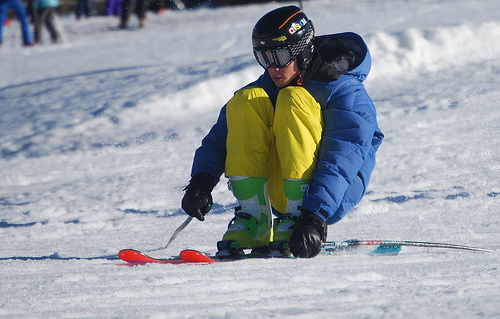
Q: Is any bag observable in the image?
A: No, there are no bags.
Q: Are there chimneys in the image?
A: No, there are no chimneys.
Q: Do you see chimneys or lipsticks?
A: No, there are no chimneys or lipsticks.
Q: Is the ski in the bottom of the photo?
A: Yes, the ski is in the bottom of the image.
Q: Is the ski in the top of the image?
A: No, the ski is in the bottom of the image.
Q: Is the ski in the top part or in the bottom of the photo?
A: The ski is in the bottom of the image.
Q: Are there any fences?
A: No, there are no fences.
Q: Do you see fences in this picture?
A: No, there are no fences.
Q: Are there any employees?
A: No, there are no employees.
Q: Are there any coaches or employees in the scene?
A: No, there are no employees or coaches.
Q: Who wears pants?
A: The man wears pants.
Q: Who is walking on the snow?
A: The man is walking on the snow.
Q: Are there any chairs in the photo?
A: No, there are no chairs.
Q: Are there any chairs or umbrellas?
A: No, there are no chairs or umbrellas.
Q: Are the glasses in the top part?
A: Yes, the glasses are in the top of the image.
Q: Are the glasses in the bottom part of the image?
A: No, the glasses are in the top of the image.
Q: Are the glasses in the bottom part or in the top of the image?
A: The glasses are in the top of the image.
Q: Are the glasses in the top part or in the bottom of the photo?
A: The glasses are in the top of the image.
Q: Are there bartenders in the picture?
A: No, there are no bartenders.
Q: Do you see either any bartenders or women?
A: No, there are no bartenders or women.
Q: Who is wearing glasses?
A: The man is wearing glasses.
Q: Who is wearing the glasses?
A: The man is wearing glasses.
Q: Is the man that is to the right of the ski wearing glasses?
A: Yes, the man is wearing glasses.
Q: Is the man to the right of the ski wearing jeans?
A: No, the man is wearing glasses.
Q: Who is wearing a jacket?
A: The man is wearing a jacket.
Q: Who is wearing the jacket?
A: The man is wearing a jacket.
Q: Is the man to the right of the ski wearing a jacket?
A: Yes, the man is wearing a jacket.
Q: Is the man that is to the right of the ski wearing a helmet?
A: No, the man is wearing a jacket.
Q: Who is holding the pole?
A: The man is holding the pole.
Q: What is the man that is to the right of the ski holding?
A: The man is holding the pole.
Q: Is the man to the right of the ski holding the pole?
A: Yes, the man is holding the pole.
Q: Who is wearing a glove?
A: The man is wearing a glove.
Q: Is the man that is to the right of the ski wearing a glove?
A: Yes, the man is wearing a glove.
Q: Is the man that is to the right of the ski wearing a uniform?
A: No, the man is wearing a glove.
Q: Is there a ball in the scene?
A: No, there are no balls.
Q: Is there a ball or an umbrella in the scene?
A: No, there are no balls or umbrellas.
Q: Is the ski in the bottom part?
A: Yes, the ski is in the bottom of the image.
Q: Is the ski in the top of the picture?
A: No, the ski is in the bottom of the image.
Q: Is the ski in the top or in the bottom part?
A: The ski is in the bottom of the image.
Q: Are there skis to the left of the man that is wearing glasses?
A: Yes, there is a ski to the left of the man.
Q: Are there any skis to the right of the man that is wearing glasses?
A: No, the ski is to the left of the man.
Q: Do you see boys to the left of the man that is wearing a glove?
A: No, there is a ski to the left of the man.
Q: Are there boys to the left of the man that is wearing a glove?
A: No, there is a ski to the left of the man.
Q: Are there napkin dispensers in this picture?
A: No, there are no napkin dispensers.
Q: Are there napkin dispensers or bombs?
A: No, there are no napkin dispensers or bombs.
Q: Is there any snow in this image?
A: Yes, there is snow.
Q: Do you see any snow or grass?
A: Yes, there is snow.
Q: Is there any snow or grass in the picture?
A: Yes, there is snow.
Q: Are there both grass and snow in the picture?
A: No, there is snow but no grass.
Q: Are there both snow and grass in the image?
A: No, there is snow but no grass.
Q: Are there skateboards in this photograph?
A: No, there are no skateboards.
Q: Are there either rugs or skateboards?
A: No, there are no skateboards or rugs.